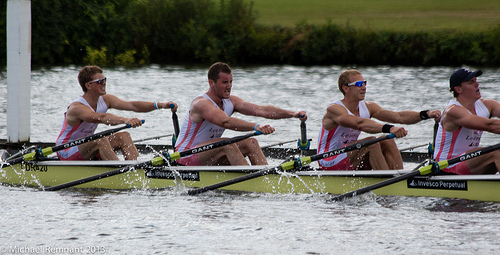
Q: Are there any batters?
A: No, there are no batters.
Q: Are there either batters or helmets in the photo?
A: No, there are no batters or helmets.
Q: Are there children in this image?
A: No, there are no children.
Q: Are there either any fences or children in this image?
A: No, there are no children or fences.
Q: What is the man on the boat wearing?
A: The man is wearing a uniform.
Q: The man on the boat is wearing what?
A: The man is wearing a uniform.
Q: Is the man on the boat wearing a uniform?
A: Yes, the man is wearing a uniform.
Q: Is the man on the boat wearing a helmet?
A: No, the man is wearing a uniform.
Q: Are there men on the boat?
A: Yes, there is a man on the boat.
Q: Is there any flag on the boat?
A: No, there is a man on the boat.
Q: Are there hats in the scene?
A: Yes, there is a hat.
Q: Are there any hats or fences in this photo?
A: Yes, there is a hat.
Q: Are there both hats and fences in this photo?
A: No, there is a hat but no fences.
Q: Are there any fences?
A: No, there are no fences.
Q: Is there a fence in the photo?
A: No, there are no fences.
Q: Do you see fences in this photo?
A: No, there are no fences.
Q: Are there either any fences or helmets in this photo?
A: No, there are no fences or helmets.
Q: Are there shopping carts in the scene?
A: No, there are no shopping carts.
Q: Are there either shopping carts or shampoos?
A: No, there are no shopping carts or shampoos.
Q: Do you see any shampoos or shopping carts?
A: No, there are no shopping carts or shampoos.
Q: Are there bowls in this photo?
A: No, there are no bowls.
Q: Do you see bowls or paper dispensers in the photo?
A: No, there are no bowls or paper dispensers.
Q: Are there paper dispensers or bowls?
A: No, there are no bowls or paper dispensers.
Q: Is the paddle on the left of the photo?
A: Yes, the paddle is on the left of the image.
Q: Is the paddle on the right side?
A: No, the paddle is on the left of the image.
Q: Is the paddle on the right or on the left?
A: The paddle is on the left of the image.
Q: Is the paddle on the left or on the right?
A: The paddle is on the left of the image.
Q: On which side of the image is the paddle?
A: The paddle is on the left of the image.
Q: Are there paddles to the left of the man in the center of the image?
A: Yes, there is a paddle to the left of the man.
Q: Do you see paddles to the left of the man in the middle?
A: Yes, there is a paddle to the left of the man.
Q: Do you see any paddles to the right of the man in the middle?
A: No, the paddle is to the left of the man.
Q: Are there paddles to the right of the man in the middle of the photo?
A: No, the paddle is to the left of the man.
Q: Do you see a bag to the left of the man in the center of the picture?
A: No, there is a paddle to the left of the man.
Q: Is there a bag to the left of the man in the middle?
A: No, there is a paddle to the left of the man.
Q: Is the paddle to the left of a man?
A: Yes, the paddle is to the left of a man.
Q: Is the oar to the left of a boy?
A: No, the oar is to the left of a man.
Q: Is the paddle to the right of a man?
A: No, the paddle is to the left of a man.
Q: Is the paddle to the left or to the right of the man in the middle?
A: The paddle is to the left of the man.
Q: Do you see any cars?
A: No, there are no cars.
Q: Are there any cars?
A: No, there are no cars.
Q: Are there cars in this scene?
A: No, there are no cars.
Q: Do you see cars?
A: No, there are no cars.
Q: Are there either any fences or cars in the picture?
A: No, there are no cars or fences.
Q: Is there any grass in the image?
A: Yes, there is grass.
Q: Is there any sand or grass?
A: Yes, there is grass.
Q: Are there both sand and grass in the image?
A: No, there is grass but no sand.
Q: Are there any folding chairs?
A: No, there are no folding chairs.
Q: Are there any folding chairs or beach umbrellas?
A: No, there are no folding chairs or beach umbrellas.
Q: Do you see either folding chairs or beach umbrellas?
A: No, there are no folding chairs or beach umbrellas.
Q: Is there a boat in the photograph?
A: Yes, there is a boat.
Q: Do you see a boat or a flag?
A: Yes, there is a boat.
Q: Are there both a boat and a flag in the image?
A: No, there is a boat but no flags.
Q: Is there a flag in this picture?
A: No, there are no flags.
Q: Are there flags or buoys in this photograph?
A: No, there are no flags or buoys.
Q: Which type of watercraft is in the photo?
A: The watercraft is a boat.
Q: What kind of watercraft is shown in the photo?
A: The watercraft is a boat.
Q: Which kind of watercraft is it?
A: The watercraft is a boat.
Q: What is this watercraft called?
A: This is a boat.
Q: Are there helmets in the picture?
A: No, there are no helmets.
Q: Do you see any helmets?
A: No, there are no helmets.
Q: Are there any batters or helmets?
A: No, there are no helmets or batters.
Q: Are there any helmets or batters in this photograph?
A: No, there are no helmets or batters.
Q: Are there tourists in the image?
A: No, there are no tourists.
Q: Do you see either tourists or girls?
A: No, there are no tourists or girls.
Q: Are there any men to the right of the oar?
A: Yes, there is a man to the right of the oar.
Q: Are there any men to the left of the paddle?
A: No, the man is to the right of the paddle.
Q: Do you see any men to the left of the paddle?
A: No, the man is to the right of the paddle.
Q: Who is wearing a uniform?
A: The man is wearing a uniform.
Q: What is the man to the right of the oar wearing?
A: The man is wearing a uniform.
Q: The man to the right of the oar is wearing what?
A: The man is wearing a uniform.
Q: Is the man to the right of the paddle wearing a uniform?
A: Yes, the man is wearing a uniform.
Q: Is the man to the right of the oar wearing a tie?
A: No, the man is wearing a uniform.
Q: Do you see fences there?
A: No, there are no fences.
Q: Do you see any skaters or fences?
A: No, there are no fences or skaters.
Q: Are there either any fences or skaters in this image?
A: No, there are no fences or skaters.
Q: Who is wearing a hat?
A: The man is wearing a hat.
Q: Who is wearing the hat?
A: The man is wearing a hat.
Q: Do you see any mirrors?
A: No, there are no mirrors.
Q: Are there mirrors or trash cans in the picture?
A: No, there are no mirrors or trash cans.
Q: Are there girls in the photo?
A: No, there are no girls.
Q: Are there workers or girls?
A: No, there are no girls or workers.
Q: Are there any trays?
A: No, there are no trays.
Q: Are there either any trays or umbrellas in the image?
A: No, there are no trays or umbrellas.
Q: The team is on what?
A: The team is on the boat.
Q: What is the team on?
A: The team is on the boat.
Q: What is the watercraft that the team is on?
A: The watercraft is a boat.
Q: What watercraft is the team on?
A: The team is on the boat.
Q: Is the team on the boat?
A: Yes, the team is on the boat.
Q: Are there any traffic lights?
A: No, there are no traffic lights.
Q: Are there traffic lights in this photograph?
A: No, there are no traffic lights.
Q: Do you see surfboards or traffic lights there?
A: No, there are no traffic lights or surfboards.